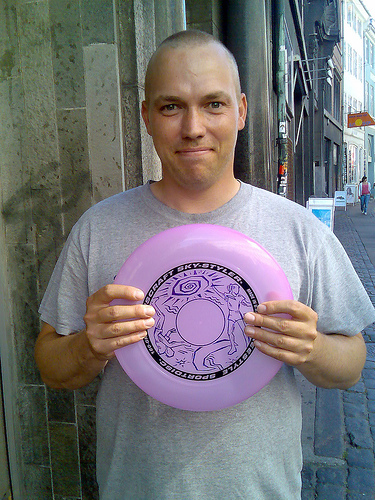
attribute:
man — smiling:
[33, 28, 369, 395]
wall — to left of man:
[3, 2, 160, 499]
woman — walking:
[356, 172, 370, 214]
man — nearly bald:
[25, 22, 370, 372]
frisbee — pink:
[69, 213, 334, 418]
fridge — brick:
[314, 403, 368, 490]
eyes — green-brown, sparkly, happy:
[157, 98, 226, 114]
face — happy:
[88, 42, 290, 224]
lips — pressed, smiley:
[174, 146, 213, 156]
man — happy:
[34, 28, 370, 494]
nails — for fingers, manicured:
[227, 295, 288, 360]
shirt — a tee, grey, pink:
[30, 174, 372, 497]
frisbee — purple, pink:
[107, 222, 293, 414]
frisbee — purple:
[93, 231, 299, 411]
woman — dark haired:
[350, 164, 370, 195]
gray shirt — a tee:
[32, 174, 373, 313]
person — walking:
[357, 175, 369, 215]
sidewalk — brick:
[324, 203, 373, 486]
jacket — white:
[340, 177, 372, 212]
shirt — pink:
[360, 180, 371, 197]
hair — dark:
[358, 176, 368, 183]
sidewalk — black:
[298, 342, 374, 500]